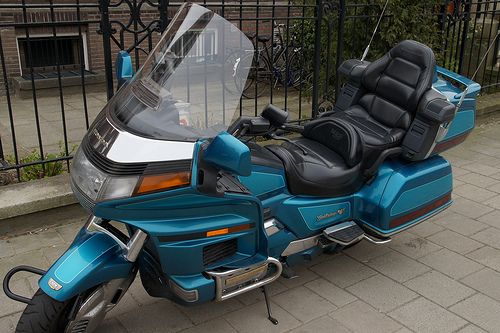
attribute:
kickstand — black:
[250, 288, 286, 327]